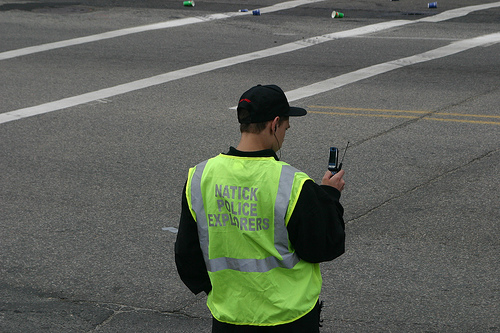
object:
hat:
[235, 83, 309, 124]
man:
[172, 83, 346, 333]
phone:
[328, 141, 351, 179]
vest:
[182, 152, 324, 327]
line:
[33, 80, 145, 108]